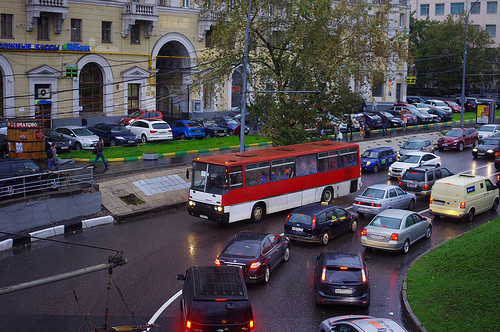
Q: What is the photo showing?
A: It is showing a road.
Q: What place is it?
A: It is a road.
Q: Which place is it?
A: It is a road.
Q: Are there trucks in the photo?
A: No, there are no trucks.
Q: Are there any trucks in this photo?
A: No, there are no trucks.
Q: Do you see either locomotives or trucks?
A: No, there are no trucks or locomotives.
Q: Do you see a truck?
A: No, there are no trucks.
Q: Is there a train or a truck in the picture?
A: No, there are no trucks or trains.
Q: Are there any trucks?
A: No, there are no trucks.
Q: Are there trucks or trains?
A: No, there are no trucks or trains.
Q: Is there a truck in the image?
A: No, there are no trucks.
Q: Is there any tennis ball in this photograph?
A: No, there are no tennis balls.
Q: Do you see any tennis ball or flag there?
A: No, there are no tennis balls or flags.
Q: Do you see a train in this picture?
A: No, there are no trains.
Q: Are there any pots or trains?
A: No, there are no trains or pots.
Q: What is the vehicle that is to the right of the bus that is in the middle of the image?
A: The vehicle is a car.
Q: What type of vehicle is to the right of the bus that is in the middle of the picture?
A: The vehicle is a car.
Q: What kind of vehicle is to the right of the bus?
A: The vehicle is a car.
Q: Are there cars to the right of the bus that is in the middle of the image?
A: Yes, there is a car to the right of the bus.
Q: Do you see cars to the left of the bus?
A: No, the car is to the right of the bus.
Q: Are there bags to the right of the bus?
A: No, there is a car to the right of the bus.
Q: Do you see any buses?
A: Yes, there is a bus.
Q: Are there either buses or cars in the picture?
A: Yes, there is a bus.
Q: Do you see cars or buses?
A: Yes, there is a bus.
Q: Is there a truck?
A: No, there are no trucks.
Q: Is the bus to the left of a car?
A: Yes, the bus is to the left of a car.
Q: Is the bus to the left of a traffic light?
A: No, the bus is to the left of a car.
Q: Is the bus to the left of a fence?
A: No, the bus is to the left of the car.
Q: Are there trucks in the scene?
A: No, there are no trucks.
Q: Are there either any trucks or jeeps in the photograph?
A: No, there are no trucks or jeeps.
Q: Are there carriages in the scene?
A: No, there are no carriages.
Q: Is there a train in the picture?
A: No, there are no trains.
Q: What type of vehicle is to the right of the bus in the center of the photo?
A: The vehicle is a car.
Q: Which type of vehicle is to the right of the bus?
A: The vehicle is a car.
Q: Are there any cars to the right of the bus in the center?
A: Yes, there is a car to the right of the bus.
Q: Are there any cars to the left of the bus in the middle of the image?
A: No, the car is to the right of the bus.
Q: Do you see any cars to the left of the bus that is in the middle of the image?
A: No, the car is to the right of the bus.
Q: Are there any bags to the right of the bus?
A: No, there is a car to the right of the bus.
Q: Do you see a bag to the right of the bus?
A: No, there is a car to the right of the bus.